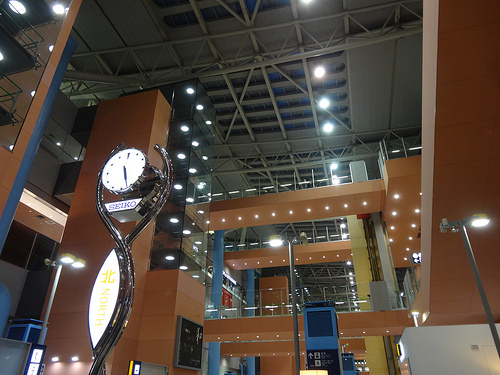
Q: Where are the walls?
A: In room.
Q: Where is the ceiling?
A: In room.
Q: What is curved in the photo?
A: Statue.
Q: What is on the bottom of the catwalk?
A: Lights.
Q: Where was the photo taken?
A: Inside building.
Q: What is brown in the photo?
A: Building.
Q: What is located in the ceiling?
A: Skylights.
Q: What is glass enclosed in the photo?
A: Observation decks.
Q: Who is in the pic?
A: No one.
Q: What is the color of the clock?
A: White.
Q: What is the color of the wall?
A: Brown.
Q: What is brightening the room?
A: Lights.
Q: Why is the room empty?
A: No One's there.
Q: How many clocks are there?
A: 1.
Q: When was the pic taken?
A: At night.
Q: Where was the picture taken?
A: In a travel hub.